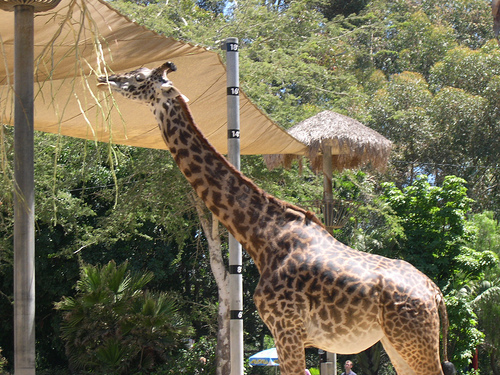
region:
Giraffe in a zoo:
[97, 62, 447, 374]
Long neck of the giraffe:
[154, 88, 296, 243]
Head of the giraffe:
[97, 60, 153, 102]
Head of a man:
[344, 359, 354, 373]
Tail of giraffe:
[439, 295, 454, 373]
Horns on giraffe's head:
[152, 62, 175, 78]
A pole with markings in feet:
[225, 35, 241, 372]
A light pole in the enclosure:
[11, 7, 34, 374]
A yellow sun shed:
[1, 1, 308, 155]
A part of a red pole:
[472, 348, 479, 368]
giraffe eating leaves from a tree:
[94, 56, 459, 373]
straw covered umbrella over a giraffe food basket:
[263, 107, 390, 244]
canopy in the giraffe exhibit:
[3, 4, 313, 369]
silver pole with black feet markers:
[213, 32, 250, 374]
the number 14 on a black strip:
[226, 127, 241, 141]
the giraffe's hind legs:
[375, 254, 442, 374]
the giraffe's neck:
[136, 103, 306, 244]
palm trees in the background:
[61, 262, 188, 374]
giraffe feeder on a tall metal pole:
[0, 2, 64, 372]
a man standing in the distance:
[343, 357, 357, 374]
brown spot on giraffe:
[160, 100, 170, 112]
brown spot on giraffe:
[163, 115, 177, 137]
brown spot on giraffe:
[177, 126, 189, 143]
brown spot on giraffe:
[187, 140, 200, 152]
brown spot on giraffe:
[172, 145, 189, 166]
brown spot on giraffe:
[210, 186, 226, 210]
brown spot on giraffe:
[223, 193, 237, 210]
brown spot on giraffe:
[326, 301, 341, 324]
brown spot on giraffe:
[286, 258, 301, 273]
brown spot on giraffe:
[266, 271, 285, 295]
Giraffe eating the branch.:
[90, 56, 463, 373]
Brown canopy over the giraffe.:
[0, 0, 320, 172]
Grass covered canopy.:
[262, 105, 397, 182]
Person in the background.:
[331, 352, 358, 374]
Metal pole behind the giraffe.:
[211, 33, 247, 374]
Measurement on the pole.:
[221, 38, 244, 55]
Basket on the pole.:
[303, 188, 365, 234]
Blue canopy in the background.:
[240, 340, 281, 365]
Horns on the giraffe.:
[146, 50, 181, 70]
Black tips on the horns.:
[158, 53, 178, 74]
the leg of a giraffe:
[274, 321, 314, 373]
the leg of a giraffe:
[395, 344, 444, 373]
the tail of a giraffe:
[434, 298, 456, 374]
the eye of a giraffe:
[132, 71, 144, 84]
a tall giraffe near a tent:
[88, 60, 448, 372]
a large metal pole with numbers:
[214, 34, 249, 373]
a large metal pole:
[13, 2, 48, 372]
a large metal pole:
[220, 35, 249, 374]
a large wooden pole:
[320, 144, 336, 373]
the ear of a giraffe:
[155, 83, 182, 100]